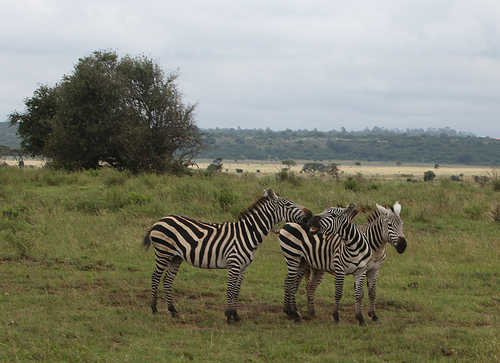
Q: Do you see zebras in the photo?
A: Yes, there is a zebra.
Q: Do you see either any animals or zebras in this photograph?
A: Yes, there is a zebra.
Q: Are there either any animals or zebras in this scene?
A: Yes, there is a zebra.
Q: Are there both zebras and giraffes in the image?
A: No, there is a zebra but no giraffes.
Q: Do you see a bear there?
A: No, there are no bears.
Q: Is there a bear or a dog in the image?
A: No, there are no bears or dogs.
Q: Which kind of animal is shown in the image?
A: The animal is a zebra.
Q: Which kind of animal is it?
A: The animal is a zebra.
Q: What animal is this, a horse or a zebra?
A: That is a zebra.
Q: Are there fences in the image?
A: No, there are no fences.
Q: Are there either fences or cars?
A: No, there are no fences or cars.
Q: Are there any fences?
A: No, there are no fences.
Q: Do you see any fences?
A: No, there are no fences.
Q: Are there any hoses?
A: No, there are no hoses.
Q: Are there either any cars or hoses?
A: No, there are no hoses or cars.